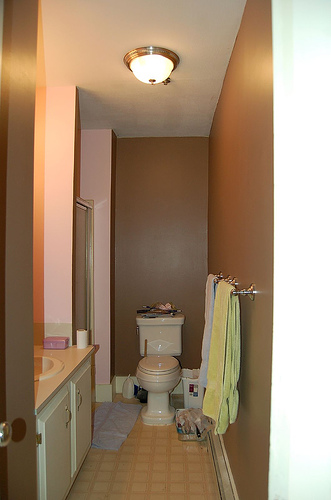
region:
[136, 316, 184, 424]
A white porcelain toilet.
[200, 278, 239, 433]
A yellow towel.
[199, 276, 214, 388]
A purple towel.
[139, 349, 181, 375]
A white porcelain toilet seat.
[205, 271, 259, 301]
A silver metal towel hanger.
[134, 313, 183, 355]
The mechanical section of the toilet.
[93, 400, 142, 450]
A purplish rug.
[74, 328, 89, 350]
A roll of toilet paper.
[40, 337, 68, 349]
A pink container.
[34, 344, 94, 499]
The bathroom sink.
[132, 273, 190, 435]
white toilet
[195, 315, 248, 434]
yellow and white towels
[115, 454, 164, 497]
Square patterned flouring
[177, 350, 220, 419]
trashcan sits beside toilet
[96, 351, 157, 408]
White bottom trim on the wall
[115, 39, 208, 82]
The light is on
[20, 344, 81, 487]
There are cabinets under the sink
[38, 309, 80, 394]
Green trim on the wall by the sink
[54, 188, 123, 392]
Shower is next to the toilet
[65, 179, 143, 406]
Sliding glass door on the shower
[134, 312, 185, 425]
White toilet in bathroom.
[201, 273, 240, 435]
Two towels hanging on towel rack.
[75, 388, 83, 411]
Handle on bathroom cabinet.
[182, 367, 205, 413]
White trashcan on floor of bathroom.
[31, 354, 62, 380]
Round sink in bathroom.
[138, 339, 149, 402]
Plunger for toilet sitting on floor.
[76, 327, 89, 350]
White roll of toilet paper sitting on counter.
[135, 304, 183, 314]
Curling iron sitting on back of commode.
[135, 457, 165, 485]
Tiles on the bathroom floor.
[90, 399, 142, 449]
White towel folded over on the bathroom floor.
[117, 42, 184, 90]
a softly glowing light fixture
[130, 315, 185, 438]
a white porclin toilet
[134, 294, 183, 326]
some clutter on the back of the toilet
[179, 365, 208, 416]
a small trash can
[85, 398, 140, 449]
blue towel on the floor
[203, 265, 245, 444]
a yellow towel on a towel rack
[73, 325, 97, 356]
roll of toilet paper sitting on the counter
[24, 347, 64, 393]
bathroom sink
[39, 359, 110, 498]
cabinet doors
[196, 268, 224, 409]
blue towel on a towel rack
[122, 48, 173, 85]
the light attached to the ceiling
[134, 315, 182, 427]
the toilet sitting next the wall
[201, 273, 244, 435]
towels hanging from the rack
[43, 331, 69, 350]
a box sitting on the counter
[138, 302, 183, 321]
tools sitting on the toilet lid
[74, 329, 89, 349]
a roll of toilet paper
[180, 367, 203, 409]
a trash can next to the toilet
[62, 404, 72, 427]
the handle on the cabinet door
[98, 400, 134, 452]
a towel laying on the bathroom floor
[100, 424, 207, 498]
the tile bathroom floor